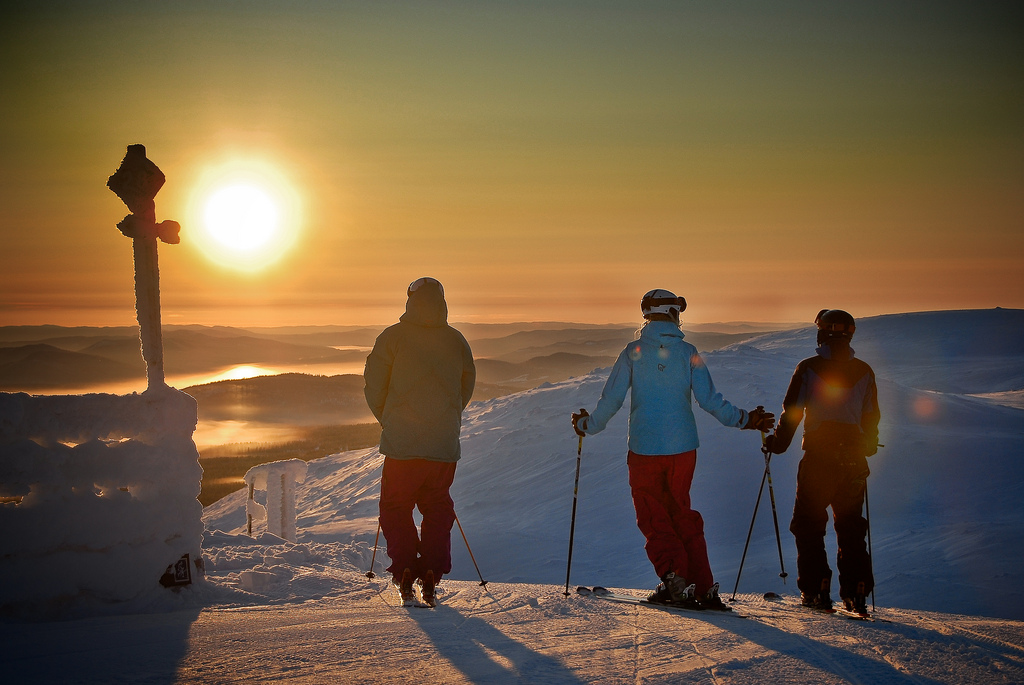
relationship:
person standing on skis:
[363, 276, 475, 606] [392, 578, 450, 616]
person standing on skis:
[573, 288, 775, 603] [570, 579, 758, 624]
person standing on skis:
[763, 309, 881, 611] [760, 587, 900, 630]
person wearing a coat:
[573, 288, 775, 603] [581, 319, 749, 459]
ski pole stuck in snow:
[367, 516, 384, 584] [12, 307, 1023, 679]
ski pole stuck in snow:
[451, 513, 489, 594] [12, 307, 1023, 679]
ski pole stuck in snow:
[561, 428, 581, 596] [12, 307, 1023, 679]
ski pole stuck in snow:
[728, 453, 774, 604] [12, 307, 1023, 679]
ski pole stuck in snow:
[863, 478, 877, 616] [12, 307, 1023, 679]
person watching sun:
[363, 276, 475, 606] [178, 152, 307, 275]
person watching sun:
[573, 288, 775, 603] [178, 152, 307, 275]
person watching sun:
[763, 309, 881, 611] [178, 152, 307, 275]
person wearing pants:
[363, 276, 475, 606] [381, 457, 455, 580]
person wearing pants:
[573, 288, 775, 603] [624, 452, 716, 589]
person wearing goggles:
[573, 288, 775, 603] [640, 294, 690, 315]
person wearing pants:
[763, 309, 881, 611] [789, 454, 876, 608]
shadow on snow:
[405, 595, 577, 683] [12, 307, 1023, 679]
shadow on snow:
[667, 604, 907, 679] [12, 307, 1023, 679]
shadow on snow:
[846, 611, 1023, 675] [12, 307, 1023, 679]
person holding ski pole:
[363, 276, 475, 606] [561, 428, 581, 596]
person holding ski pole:
[363, 276, 475, 606] [367, 516, 384, 584]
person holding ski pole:
[363, 276, 475, 606] [451, 513, 489, 594]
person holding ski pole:
[573, 288, 775, 603] [561, 428, 581, 596]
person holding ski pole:
[573, 288, 775, 603] [754, 433, 792, 580]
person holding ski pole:
[763, 309, 881, 611] [728, 453, 774, 604]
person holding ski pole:
[763, 309, 881, 611] [863, 478, 877, 616]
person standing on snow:
[363, 276, 475, 606] [12, 307, 1023, 679]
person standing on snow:
[573, 288, 775, 603] [12, 307, 1023, 679]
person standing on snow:
[763, 309, 881, 611] [12, 307, 1023, 679]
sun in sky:
[178, 152, 307, 275] [0, 4, 1021, 334]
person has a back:
[363, 276, 475, 606] [381, 323, 462, 458]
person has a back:
[573, 288, 775, 603] [625, 330, 697, 463]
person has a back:
[763, 309, 881, 611] [802, 349, 866, 461]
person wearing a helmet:
[763, 309, 881, 611] [812, 309, 858, 346]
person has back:
[363, 276, 475, 606] [381, 323, 462, 458]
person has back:
[573, 288, 775, 603] [625, 330, 697, 463]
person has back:
[763, 309, 881, 611] [802, 349, 866, 461]